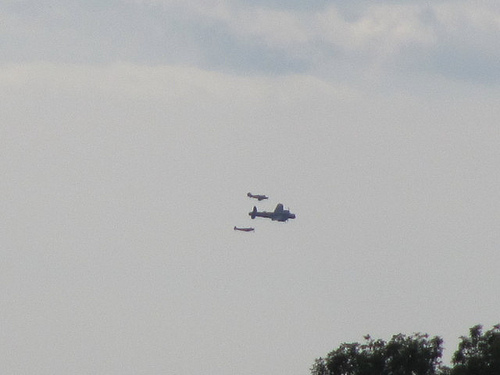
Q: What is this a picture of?
A: Planes.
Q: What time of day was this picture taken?
A: Daytime.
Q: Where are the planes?
A: In the sky.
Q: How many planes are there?
A: Three.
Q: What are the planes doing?
A: Flying.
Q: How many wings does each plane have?
A: Two.